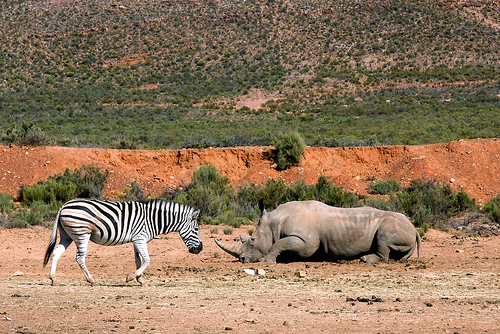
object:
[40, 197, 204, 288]
zebra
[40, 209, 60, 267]
tail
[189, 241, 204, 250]
nose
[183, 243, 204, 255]
mouth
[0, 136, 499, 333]
dirt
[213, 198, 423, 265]
rhinocerous